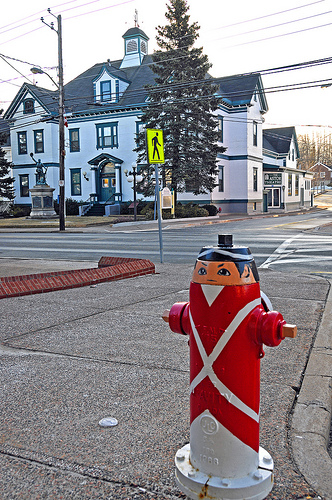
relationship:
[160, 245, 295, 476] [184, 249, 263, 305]
firehydrant resembles character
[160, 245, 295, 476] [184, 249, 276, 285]
firehydrant has face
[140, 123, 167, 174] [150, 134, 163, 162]
sign has man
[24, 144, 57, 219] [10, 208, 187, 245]
statue on ground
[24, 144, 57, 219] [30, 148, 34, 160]
statue holds something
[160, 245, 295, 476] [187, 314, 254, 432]
firehydrant has x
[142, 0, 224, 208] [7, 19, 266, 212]
tree in front of house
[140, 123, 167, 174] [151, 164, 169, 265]
sign has metal pole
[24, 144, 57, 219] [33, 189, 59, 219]
statue has base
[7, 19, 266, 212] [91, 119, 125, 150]
house has window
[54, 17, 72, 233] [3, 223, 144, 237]
telephone pole on sidewalk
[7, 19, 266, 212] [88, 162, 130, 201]
house has door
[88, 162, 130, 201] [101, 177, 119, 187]
door has glass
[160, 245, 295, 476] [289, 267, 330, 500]
firehydrant by curb